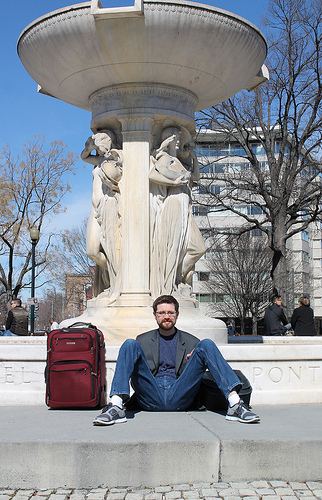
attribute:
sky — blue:
[0, 0, 322, 304]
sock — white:
[227, 388, 240, 407]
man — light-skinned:
[91, 292, 263, 423]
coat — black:
[289, 305, 315, 334]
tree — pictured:
[1, 129, 83, 325]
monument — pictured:
[81, 111, 193, 294]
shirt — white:
[153, 328, 178, 375]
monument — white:
[17, 0, 270, 295]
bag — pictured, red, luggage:
[45, 319, 110, 409]